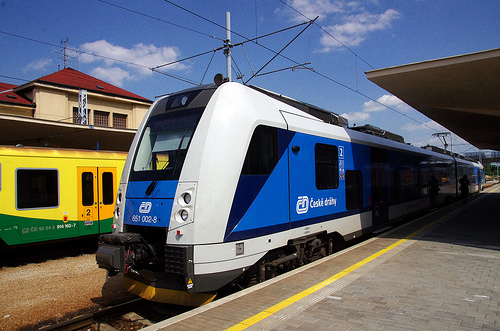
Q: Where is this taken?
A: A train station.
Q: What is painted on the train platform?
A: A yellow line.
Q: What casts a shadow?
A: The roof of station.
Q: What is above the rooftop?
A: Blue sky and white clouds.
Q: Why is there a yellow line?
A: To advise caution.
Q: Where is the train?
A: At the station.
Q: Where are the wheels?
A: Under the train.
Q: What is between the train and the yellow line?
A: Red bricks.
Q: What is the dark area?
A: Shade from overhang.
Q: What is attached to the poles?
A: Electrical wires.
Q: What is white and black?
A: Top of train.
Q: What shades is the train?
A: Yellow, gold, and green.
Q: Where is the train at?
A: Train station.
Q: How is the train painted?
A: White and blue.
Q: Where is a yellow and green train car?
A: Beside the blue and white train.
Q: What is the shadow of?
A: The roof.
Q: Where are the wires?
A: Hanging over the train.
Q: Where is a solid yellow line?
A: On the platform.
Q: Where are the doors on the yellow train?
A: Beside the window.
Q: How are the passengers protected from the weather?
A: Overhang on the platform.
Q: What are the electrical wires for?
A: The train.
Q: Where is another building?
A: Other side of the yellow train.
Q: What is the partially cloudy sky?
A: Blue.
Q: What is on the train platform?
A: Yellow stripe.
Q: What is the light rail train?
A: Blue and white.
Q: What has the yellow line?
A: The brick train platform.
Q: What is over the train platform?
A: The roof.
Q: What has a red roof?
A: The building.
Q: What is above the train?
A: The power lines.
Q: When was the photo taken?
A: Daytime.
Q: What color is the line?
A: Yellow.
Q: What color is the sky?
A: Blue.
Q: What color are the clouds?
A: White.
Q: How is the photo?
A: Clear.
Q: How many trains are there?
A: Two.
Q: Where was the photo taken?
A: Railway station.